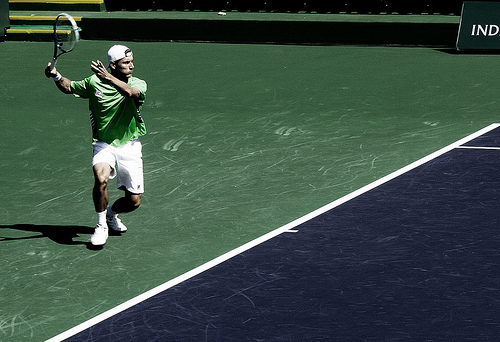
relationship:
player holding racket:
[67, 39, 166, 246] [37, 4, 81, 92]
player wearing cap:
[67, 39, 166, 246] [93, 39, 149, 71]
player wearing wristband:
[67, 39, 166, 246] [50, 71, 72, 84]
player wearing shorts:
[67, 39, 166, 246] [70, 142, 158, 216]